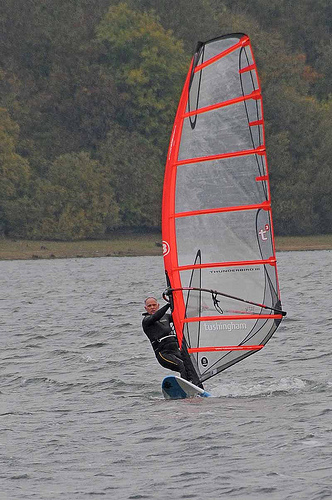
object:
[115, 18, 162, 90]
foliage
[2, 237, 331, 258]
shore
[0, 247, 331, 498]
ocean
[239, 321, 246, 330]
letter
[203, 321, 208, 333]
letter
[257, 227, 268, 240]
t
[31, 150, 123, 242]
green tree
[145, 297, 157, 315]
face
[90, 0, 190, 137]
trees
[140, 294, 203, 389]
man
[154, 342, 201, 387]
pants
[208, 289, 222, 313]
rope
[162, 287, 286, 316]
black bar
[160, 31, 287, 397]
boat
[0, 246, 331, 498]
choppy water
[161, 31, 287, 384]
sail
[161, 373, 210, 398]
panel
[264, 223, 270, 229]
3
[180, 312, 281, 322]
bar